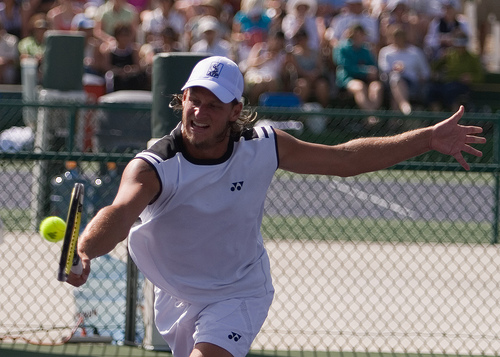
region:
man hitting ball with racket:
[27, 92, 257, 314]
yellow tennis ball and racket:
[15, 178, 122, 312]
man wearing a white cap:
[177, 58, 254, 116]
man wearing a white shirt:
[125, 118, 302, 294]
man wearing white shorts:
[135, 278, 282, 353]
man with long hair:
[162, 69, 279, 159]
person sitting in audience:
[245, 25, 300, 123]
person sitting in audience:
[278, 26, 344, 132]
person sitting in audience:
[372, 18, 444, 129]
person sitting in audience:
[334, 13, 383, 128]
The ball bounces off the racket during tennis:
[36, 219, 68, 246]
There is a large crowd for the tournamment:
[328, 18, 407, 105]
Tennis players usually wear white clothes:
[146, 150, 271, 352]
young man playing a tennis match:
[32, 48, 280, 282]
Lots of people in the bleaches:
[255, 6, 496, 105]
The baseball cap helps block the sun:
[185, 56, 250, 110]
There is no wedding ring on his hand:
[425, 111, 487, 175]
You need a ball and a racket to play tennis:
[27, 169, 95, 286]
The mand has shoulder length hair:
[231, 93, 261, 138]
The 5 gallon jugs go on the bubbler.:
[50, 159, 123, 212]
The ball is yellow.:
[34, 208, 66, 247]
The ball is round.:
[32, 206, 64, 248]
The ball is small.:
[34, 213, 67, 242]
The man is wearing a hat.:
[167, 59, 261, 160]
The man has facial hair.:
[164, 51, 256, 148]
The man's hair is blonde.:
[163, 57, 260, 158]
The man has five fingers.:
[420, 93, 488, 178]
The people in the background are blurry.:
[289, 3, 452, 98]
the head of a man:
[157, 37, 274, 152]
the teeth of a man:
[162, 116, 234, 154]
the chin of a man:
[179, 126, 212, 152]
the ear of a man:
[213, 77, 261, 130]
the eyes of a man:
[181, 78, 273, 120]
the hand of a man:
[403, 90, 496, 153]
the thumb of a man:
[413, 86, 484, 158]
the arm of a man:
[223, 115, 426, 186]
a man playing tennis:
[31, 45, 286, 282]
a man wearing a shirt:
[123, 110, 303, 314]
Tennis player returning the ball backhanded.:
[24, 33, 481, 354]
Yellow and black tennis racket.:
[56, 169, 88, 279]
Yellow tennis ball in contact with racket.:
[34, 181, 88, 281]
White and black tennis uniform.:
[124, 122, 284, 349]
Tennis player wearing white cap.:
[182, 46, 257, 151]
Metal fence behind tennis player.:
[4, 145, 486, 355]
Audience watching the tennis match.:
[13, 9, 498, 78]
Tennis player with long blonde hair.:
[162, 61, 262, 143]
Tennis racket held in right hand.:
[30, 161, 155, 278]